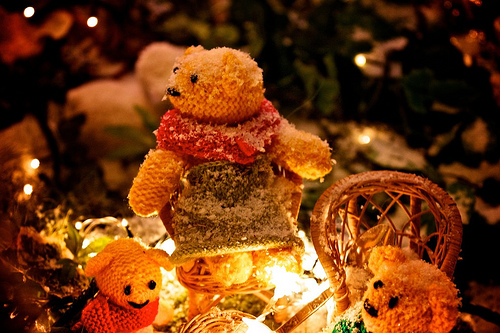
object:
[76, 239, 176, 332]
bear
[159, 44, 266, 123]
head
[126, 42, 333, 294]
decoration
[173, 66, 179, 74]
eye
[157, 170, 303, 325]
chair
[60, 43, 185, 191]
bear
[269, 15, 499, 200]
christmas tree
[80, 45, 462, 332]
animal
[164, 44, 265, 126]
ball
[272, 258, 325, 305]
christmas light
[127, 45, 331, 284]
yarn bear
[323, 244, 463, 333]
yarn bear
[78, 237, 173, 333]
yarn bear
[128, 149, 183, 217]
arm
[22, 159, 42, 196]
light bulbs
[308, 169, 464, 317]
chair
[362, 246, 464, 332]
bear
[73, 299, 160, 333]
scarf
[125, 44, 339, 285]
bear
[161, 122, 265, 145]
snow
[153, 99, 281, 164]
scarf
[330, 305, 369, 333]
scarf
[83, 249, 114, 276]
ear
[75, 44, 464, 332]
dolls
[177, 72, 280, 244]
yarn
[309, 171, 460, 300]
wicker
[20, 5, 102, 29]
lights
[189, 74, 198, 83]
eye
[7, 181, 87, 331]
flower decoration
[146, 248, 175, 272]
ear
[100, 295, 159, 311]
bear's neck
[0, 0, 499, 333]
camera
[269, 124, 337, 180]
arm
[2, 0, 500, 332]
table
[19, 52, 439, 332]
piece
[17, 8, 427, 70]
string